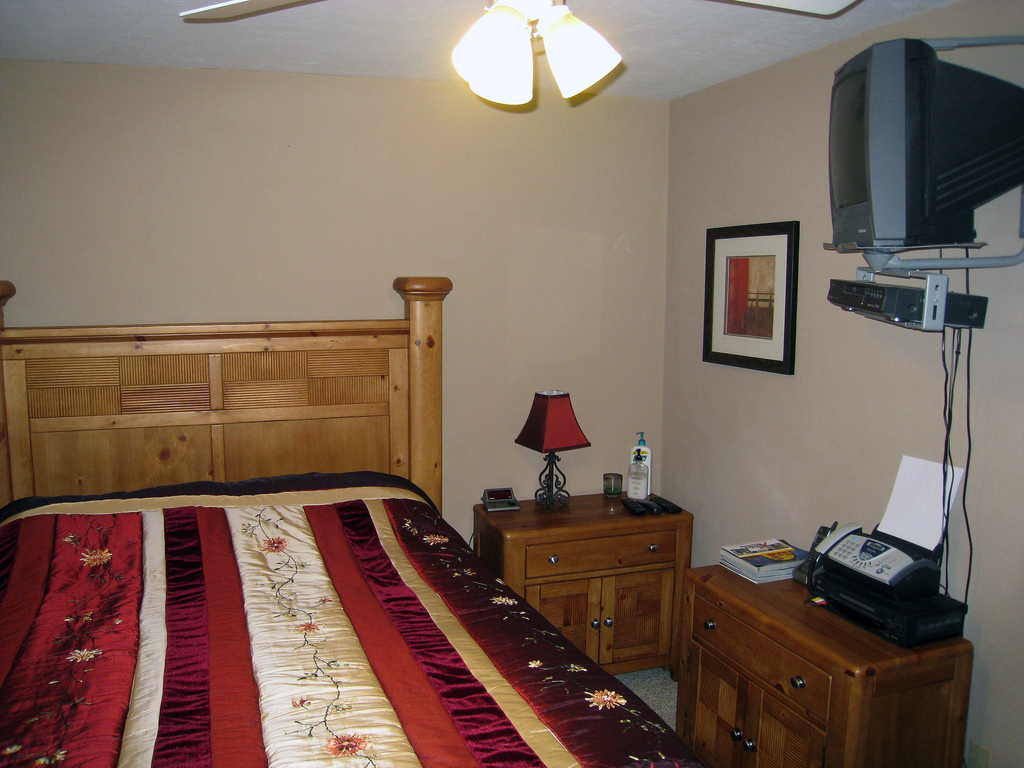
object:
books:
[717, 538, 819, 584]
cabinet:
[666, 541, 976, 765]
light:
[451, 0, 623, 106]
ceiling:
[0, 0, 958, 104]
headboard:
[0, 276, 455, 517]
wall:
[0, 59, 673, 551]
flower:
[583, 685, 633, 713]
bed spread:
[0, 474, 703, 767]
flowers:
[408, 548, 479, 604]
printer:
[807, 523, 969, 649]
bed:
[0, 274, 698, 766]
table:
[473, 488, 697, 677]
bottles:
[627, 431, 654, 500]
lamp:
[514, 389, 593, 506]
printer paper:
[873, 455, 964, 553]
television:
[821, 34, 1023, 257]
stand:
[852, 241, 1024, 333]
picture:
[701, 219, 800, 375]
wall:
[662, 0, 1023, 766]